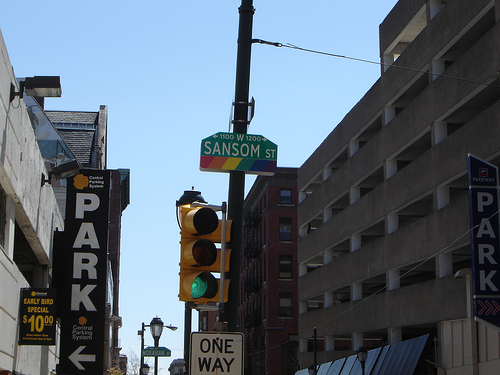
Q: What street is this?
A: Sansom Street.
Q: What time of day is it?
A: Morning.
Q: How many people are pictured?
A: None.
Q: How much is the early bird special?
A: $10.00.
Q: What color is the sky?
A: Blue.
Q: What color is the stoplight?
A: Green.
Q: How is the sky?
A: Clear.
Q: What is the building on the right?
A: Parking garage.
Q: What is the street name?
A: Sansom.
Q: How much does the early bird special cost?
A: $10.00.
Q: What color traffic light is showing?
A: Green.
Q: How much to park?
A: 10.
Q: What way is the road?
A: One way.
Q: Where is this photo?
A: Sansom St.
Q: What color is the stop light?
A: Green.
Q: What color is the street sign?
A: Rainbow.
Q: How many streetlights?
A: 5.